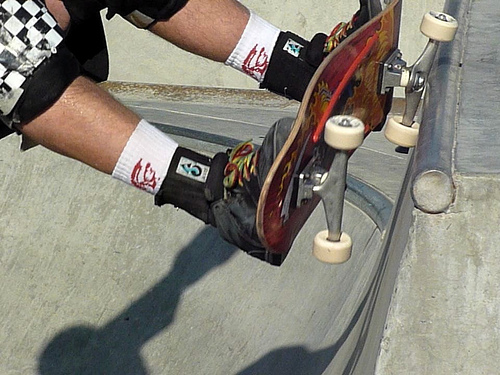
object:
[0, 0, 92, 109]
kneepad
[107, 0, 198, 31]
kneepad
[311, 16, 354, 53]
strings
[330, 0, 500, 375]
curb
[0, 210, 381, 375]
concrete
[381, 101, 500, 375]
concrete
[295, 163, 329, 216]
silver bolt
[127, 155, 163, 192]
design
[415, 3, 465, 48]
wheel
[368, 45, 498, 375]
wall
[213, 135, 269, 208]
lace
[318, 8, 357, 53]
shoelaces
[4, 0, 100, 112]
knee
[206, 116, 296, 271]
shoe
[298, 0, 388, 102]
shoe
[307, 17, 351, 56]
laces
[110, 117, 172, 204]
socks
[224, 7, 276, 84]
socks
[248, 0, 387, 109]
man's feet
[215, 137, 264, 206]
braces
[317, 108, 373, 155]
wheel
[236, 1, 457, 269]
skateboard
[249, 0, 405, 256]
board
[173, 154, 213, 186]
arrow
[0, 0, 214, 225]
leg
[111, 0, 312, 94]
leg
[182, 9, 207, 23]
hair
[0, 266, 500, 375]
pavement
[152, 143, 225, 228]
ankle brace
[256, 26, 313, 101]
ankle brace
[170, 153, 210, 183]
logo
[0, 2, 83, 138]
kneepad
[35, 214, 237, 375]
shadow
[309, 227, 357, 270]
wheel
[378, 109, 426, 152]
wheel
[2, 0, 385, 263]
man